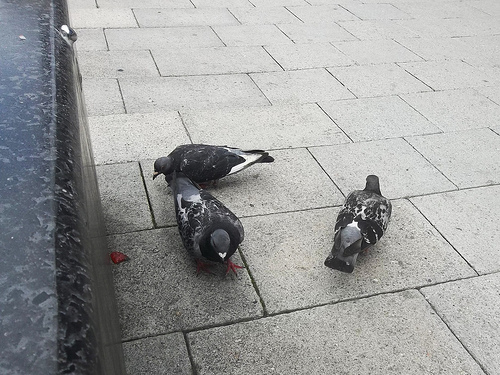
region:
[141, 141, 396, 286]
the pigeons on a sidewalk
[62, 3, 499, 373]
brick patterned pavers on the ground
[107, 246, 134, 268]
piece of food on the ground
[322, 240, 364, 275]
tail of a pigeon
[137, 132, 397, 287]
three pigeons scrounging for food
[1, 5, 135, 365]
metal post on the ground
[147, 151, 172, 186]
head of a pigeon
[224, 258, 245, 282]
left foot of a pigeon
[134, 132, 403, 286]
three pigeons on the ground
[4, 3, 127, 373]
black divider on the ground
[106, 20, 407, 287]
three doves are on the ground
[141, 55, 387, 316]
they are black in colour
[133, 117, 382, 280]
they have white stripes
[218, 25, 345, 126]
the floor is brown in colour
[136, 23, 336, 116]
the floor is squared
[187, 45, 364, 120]
it has rectangular slabs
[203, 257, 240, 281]
the legs are red in colour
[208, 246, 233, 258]
the beak is white in colour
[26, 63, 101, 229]
the wall is black and shiny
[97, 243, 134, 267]
the red pepper is on the ground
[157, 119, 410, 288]
the birds are three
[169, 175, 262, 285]
the bird is black and grey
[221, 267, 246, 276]
the feet are red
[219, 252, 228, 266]
th ebeak is black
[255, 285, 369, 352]
tiles are made of concrete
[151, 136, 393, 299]
the birds are loking for food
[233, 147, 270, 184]
the tail is white and grey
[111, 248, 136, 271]
the pedal is red in color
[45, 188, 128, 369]
the wall is smooth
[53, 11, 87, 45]
bird droppings are on the wall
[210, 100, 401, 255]
these are small birds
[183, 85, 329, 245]
the birds are black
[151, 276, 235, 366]
this is a stone path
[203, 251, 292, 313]
these are small feet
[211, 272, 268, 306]
the feet are red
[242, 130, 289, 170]
this is a tail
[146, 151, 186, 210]
this is a head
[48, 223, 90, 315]
this is a stone curb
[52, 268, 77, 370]
the curb is black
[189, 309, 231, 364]
this is a crack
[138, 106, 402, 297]
pigeons are on the sidewalk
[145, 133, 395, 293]
the pigeons are looking for food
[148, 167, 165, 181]
the pigeon has a black and white beak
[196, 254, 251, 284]
the pigeon's feet are orange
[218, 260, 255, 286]
the pigeon's claws are black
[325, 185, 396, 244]
the pigeon has speckled wing feathers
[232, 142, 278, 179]
black and white tail feathers are on the pigeon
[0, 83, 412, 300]
the pigeons are near a marble wall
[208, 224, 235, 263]
the head of the pigeon is gray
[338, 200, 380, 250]
white feathers are under the wings